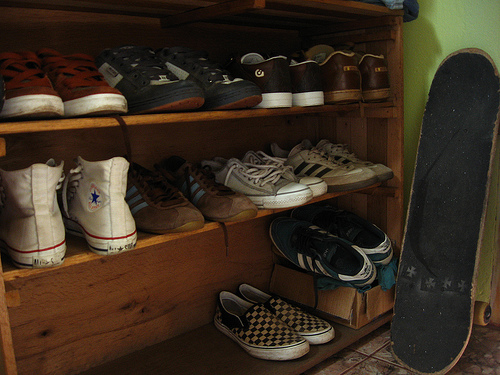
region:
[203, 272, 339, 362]
A pair of black/white checkered shoes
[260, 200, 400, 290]
A blue/white pair of shoes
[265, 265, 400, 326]
A small cardboard box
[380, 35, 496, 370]
A skateboard leaning on a wall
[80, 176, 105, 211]
A blue/red star logo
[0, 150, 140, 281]
A pair of white shoes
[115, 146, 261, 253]
A pair of brown/light blue shoes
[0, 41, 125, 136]
A pair of old red shoes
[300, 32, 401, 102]
A pair of brown.tan shoes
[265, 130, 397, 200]
A pair of black/white shoes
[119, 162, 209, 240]
a brown shoe on the shelf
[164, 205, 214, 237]
the toe of a shoe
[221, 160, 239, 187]
a white shoe lace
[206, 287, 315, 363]
a black and white checkered shoe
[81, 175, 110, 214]
a logo on the shoe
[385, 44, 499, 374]
a black skateboard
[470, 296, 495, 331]
a wheel under the skateboard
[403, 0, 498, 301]
a green wall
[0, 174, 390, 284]
a brown wooden shelf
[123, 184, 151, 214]
blue stripes on the shoe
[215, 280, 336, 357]
a pair of checkered pattern shoes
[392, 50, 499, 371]
a skateboard with black decking tape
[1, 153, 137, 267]
a pair of white high-top converse tennis shoes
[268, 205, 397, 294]
a pair of blue and white tennis shoes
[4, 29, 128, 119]
a pair of red shoes with white bottoms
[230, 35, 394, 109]
two pairs of brown shoes beside one another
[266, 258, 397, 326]
an old small cardboard box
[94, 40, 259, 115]
a dark grey pair of skateboard shoes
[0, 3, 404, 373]
a three shelf shoe rack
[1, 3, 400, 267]
two full rows of shoes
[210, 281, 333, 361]
checkered loafers on shelf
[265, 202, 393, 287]
blue sneakers in box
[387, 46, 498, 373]
skateboard leaning against wall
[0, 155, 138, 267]
white tennis shoes on shelf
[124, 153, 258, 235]
brown tennis shoes on shelf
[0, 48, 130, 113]
red tennis shoes on shelf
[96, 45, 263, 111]
black tennis shoes on shelf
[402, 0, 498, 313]
bright green wall of room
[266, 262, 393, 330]
brown cardboard box on shelf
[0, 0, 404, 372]
wood shelf with shoes on it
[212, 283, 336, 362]
Dirty, checkerboard Vans on the bottom shelf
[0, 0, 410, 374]
A wooden shoe rack with three levels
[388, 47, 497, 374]
A black skateboarding leaning against the wall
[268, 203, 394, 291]
Blue and white shoes on a small box on the bottom shelf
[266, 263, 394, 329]
A small cardboard box on the bottom shelf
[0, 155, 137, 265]
Dirty white high-top converse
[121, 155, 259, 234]
Brown and blue striped shoes on the second shelf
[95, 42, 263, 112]
Black padded skater shoes on the top shelf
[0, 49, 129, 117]
Red and white dirty padded skater shoes on the top shelf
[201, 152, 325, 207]
Low grey and white shoes on the second shelf